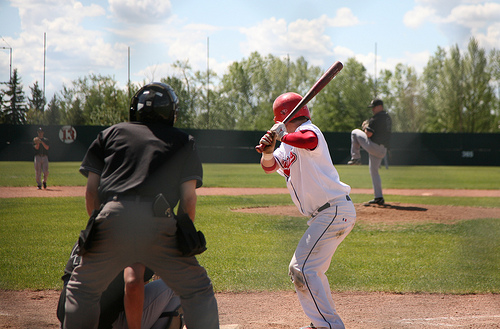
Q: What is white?
A: Batter's uniform.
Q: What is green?
A: Grass.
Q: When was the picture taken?
A: Daytime.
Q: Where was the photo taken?
A: At a baseball game.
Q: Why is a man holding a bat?
A: To hit a ball.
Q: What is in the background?
A: Trees.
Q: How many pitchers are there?
A: One.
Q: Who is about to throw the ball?
A: The pitcher.